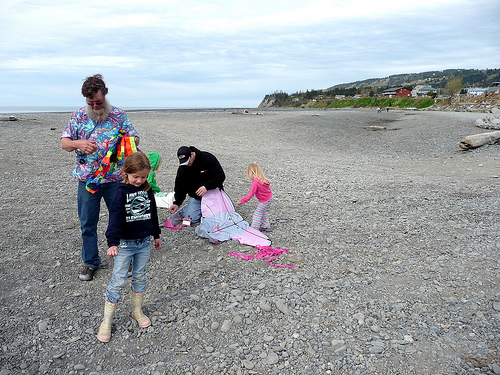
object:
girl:
[97, 149, 166, 345]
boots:
[133, 291, 155, 327]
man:
[60, 75, 142, 280]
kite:
[81, 134, 137, 192]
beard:
[84, 100, 113, 125]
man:
[168, 142, 229, 223]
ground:
[1, 105, 500, 374]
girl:
[238, 161, 278, 230]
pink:
[237, 175, 277, 208]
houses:
[465, 83, 500, 99]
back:
[251, 0, 499, 111]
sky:
[0, 0, 500, 115]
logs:
[473, 114, 499, 130]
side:
[477, 112, 500, 372]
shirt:
[236, 177, 271, 206]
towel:
[83, 134, 141, 196]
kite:
[194, 188, 273, 248]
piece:
[457, 127, 500, 152]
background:
[1, 0, 495, 111]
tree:
[444, 75, 465, 94]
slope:
[259, 89, 286, 107]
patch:
[321, 90, 431, 113]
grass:
[328, 90, 436, 111]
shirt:
[63, 109, 139, 181]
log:
[461, 129, 500, 153]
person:
[385, 103, 391, 113]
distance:
[0, 0, 499, 173]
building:
[384, 84, 411, 97]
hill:
[259, 67, 499, 113]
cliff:
[256, 67, 499, 111]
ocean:
[4, 105, 261, 116]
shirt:
[103, 182, 160, 244]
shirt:
[170, 148, 226, 205]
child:
[142, 148, 168, 192]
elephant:
[195, 190, 275, 248]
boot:
[92, 302, 116, 341]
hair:
[249, 158, 270, 188]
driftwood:
[477, 110, 499, 127]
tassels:
[231, 244, 297, 268]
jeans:
[107, 238, 154, 303]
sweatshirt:
[147, 152, 162, 192]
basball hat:
[175, 145, 194, 165]